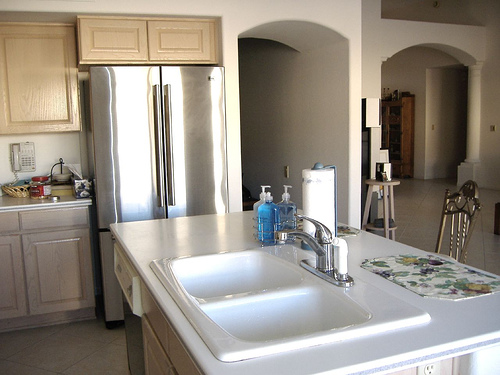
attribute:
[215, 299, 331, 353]
sink — double, white, clean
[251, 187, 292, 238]
bottles — pump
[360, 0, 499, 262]
room — adjacent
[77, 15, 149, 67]
cabinet — small, tan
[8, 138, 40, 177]
phone — white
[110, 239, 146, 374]
dishwasher — silver, white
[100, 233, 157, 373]
dishwasher — white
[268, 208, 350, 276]
faucet — silver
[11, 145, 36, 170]
phone — white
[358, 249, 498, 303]
mat — floral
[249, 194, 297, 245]
soap — blue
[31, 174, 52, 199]
jar — plastic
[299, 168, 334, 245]
towels — paper, white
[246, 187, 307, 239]
bottles — several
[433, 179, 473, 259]
chair — brown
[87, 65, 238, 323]
fridge — silver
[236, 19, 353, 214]
doorway — arched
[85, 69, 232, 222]
refrigerator — stainless steel, large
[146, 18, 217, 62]
cabinet — small, tan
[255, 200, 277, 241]
soap — blue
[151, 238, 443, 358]
sink — porcelain, white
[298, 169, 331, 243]
towels — paper